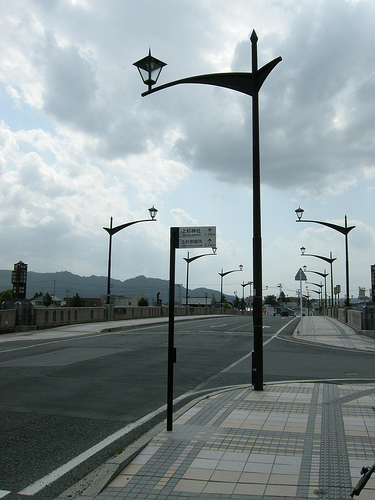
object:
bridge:
[0, 298, 242, 331]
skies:
[0, 8, 372, 297]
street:
[0, 306, 375, 500]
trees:
[69, 290, 83, 311]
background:
[0, 202, 374, 319]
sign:
[166, 218, 219, 254]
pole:
[163, 225, 181, 435]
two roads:
[81, 311, 375, 500]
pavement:
[0, 313, 301, 500]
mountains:
[122, 270, 188, 306]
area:
[0, 309, 241, 342]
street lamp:
[135, 28, 285, 398]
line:
[14, 391, 187, 496]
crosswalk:
[294, 303, 375, 357]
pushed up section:
[98, 303, 239, 333]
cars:
[272, 308, 283, 319]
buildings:
[60, 290, 103, 310]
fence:
[34, 299, 247, 328]